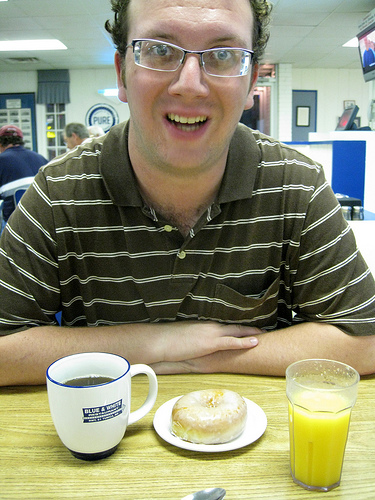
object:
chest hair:
[156, 205, 202, 237]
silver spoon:
[179, 484, 227, 497]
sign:
[297, 107, 309, 125]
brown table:
[13, 422, 63, 483]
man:
[1, 124, 51, 231]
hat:
[0, 124, 22, 136]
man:
[1, 1, 373, 391]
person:
[63, 122, 104, 149]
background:
[0, 0, 375, 233]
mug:
[46, 350, 159, 461]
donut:
[169, 386, 247, 444]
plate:
[153, 390, 269, 452]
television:
[352, 13, 375, 85]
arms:
[0, 175, 373, 383]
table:
[1, 373, 374, 499]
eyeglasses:
[126, 38, 258, 78]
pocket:
[217, 274, 282, 324]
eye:
[147, 40, 175, 62]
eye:
[208, 44, 235, 62]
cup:
[45, 351, 158, 460]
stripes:
[48, 186, 114, 262]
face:
[121, 0, 257, 171]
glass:
[285, 356, 360, 492]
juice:
[290, 401, 349, 487]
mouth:
[161, 107, 210, 143]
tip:
[183, 482, 226, 500]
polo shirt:
[0, 116, 375, 336]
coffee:
[60, 374, 117, 386]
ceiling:
[2, 2, 374, 70]